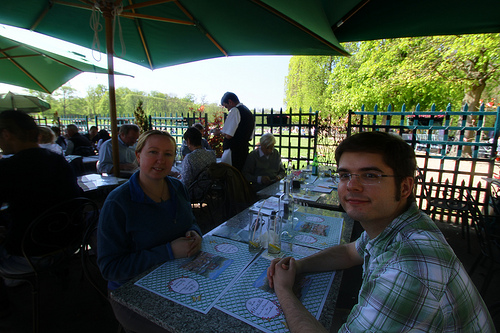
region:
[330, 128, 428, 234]
man with brown hair wearing glasses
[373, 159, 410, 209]
side burn on side of man's face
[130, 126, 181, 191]
blonde haired woman with it pulled back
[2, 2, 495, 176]
green canopies covering dining area in restaurant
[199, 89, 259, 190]
waiter dressed in black and white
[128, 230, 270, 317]
place mat at restaurant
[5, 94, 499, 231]
green metal fence used to enclose restaurant's dining area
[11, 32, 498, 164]
trees growing outside of restaurant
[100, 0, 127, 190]
brown metal pole holding up canopy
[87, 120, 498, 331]
man and woman sitting at table in outdoor restaurant table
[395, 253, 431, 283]
the shirt is plaid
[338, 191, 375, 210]
the guy is smiling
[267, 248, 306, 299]
the guy has his hands on the table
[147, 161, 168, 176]
the lady is smiling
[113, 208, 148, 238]
the jacket is blue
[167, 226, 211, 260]
the lady has her hands on the table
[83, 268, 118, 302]
the lady is sitting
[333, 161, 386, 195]
the guy is wearing glasses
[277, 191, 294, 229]
the bottle is clear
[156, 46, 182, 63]
the umbrella is green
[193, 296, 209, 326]
part of a table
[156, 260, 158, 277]
edge of a table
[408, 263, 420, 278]
part of a shirt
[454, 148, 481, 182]
part of a fence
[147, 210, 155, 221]
part of a sweater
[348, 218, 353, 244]
part of an arm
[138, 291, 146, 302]
edge of a table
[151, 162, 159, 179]
face of a woman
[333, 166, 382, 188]
the man is wearing glasses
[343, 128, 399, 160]
the man has black hair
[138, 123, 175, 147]
the woman has blonde hair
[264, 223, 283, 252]
a glass is on the table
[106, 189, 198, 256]
the woman is wearing a blue top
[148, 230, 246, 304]
a menu on the table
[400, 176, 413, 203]
it is the ear of the man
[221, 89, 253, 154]
a waiter in the background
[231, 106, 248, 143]
a waiter in a black vest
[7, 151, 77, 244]
man in a black chair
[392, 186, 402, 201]
part of a cheek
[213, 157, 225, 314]
part of a table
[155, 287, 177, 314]
edge of a table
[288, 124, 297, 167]
part of a fence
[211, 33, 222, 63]
part of a roof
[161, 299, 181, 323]
edge of a table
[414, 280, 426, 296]
part of a shirt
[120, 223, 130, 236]
part of a sweater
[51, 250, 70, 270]
part of a chair